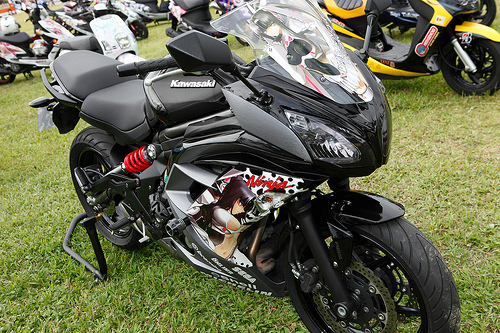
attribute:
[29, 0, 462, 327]
motorcycle — parked, white, sitting, red, black, silver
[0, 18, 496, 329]
grass — green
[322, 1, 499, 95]
motorcycle — parked, yellow, black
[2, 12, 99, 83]
motorcycle — parked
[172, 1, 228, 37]
motorcycle — parked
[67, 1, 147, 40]
scooter — parked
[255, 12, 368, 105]
girl — printed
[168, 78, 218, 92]
word — silver